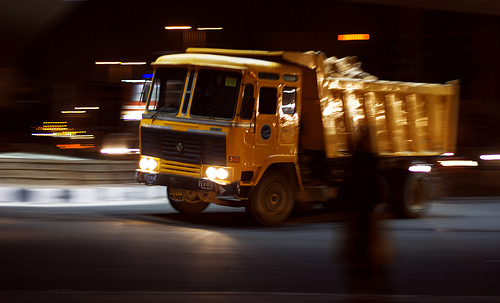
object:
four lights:
[139, 157, 229, 179]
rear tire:
[392, 165, 434, 219]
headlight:
[206, 167, 228, 180]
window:
[146, 67, 188, 114]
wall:
[367, 103, 438, 149]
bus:
[135, 48, 458, 226]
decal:
[261, 124, 272, 140]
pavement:
[0, 198, 500, 303]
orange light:
[338, 34, 371, 41]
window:
[190, 68, 242, 119]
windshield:
[147, 67, 241, 120]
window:
[283, 86, 297, 113]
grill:
[141, 126, 227, 166]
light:
[139, 157, 157, 171]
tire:
[245, 174, 294, 225]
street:
[0, 195, 500, 303]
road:
[1, 195, 500, 303]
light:
[337, 34, 369, 41]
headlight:
[139, 158, 157, 171]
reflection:
[36, 215, 242, 290]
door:
[252, 81, 277, 155]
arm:
[249, 85, 278, 155]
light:
[206, 166, 228, 178]